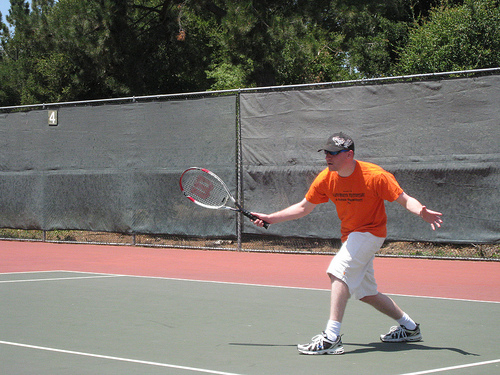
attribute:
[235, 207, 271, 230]
handle — black 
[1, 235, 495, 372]
court — green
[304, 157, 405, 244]
shirt — orange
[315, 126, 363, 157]
cap — black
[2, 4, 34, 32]
skies — blue 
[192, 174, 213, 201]
logo — red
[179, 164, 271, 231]
racket — red and white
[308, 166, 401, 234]
t-shirt — orange, bright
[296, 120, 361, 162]
hat — black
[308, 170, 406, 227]
shirt — orange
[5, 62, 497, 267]
fence — metal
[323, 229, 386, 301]
shorts — knee length, white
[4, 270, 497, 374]
tennis court — green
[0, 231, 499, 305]
border — red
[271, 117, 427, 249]
shirt — orange 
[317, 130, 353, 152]
cap — black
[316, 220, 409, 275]
shorts — white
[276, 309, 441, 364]
sneaker — black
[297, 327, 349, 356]
stripes — white